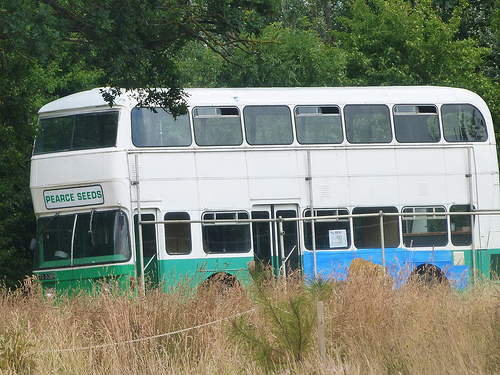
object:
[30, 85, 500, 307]
bus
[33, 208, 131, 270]
windshield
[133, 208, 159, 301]
door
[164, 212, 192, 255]
window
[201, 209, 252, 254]
window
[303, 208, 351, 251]
window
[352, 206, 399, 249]
window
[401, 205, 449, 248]
window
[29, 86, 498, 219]
levels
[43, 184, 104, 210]
letters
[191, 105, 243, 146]
window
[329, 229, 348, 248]
object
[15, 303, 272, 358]
wire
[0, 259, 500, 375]
grass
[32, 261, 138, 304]
bumper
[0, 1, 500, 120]
trees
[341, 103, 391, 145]
windows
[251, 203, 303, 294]
door